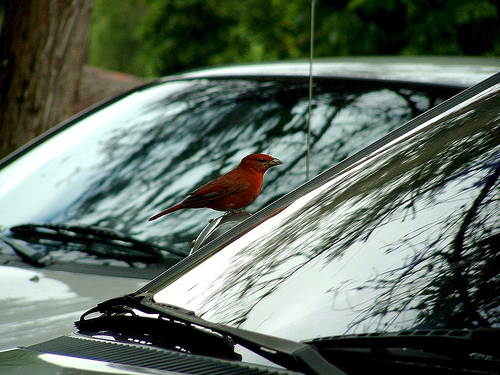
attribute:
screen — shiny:
[90, 74, 499, 374]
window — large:
[1, 80, 484, 292]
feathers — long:
[145, 200, 182, 229]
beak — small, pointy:
[269, 156, 284, 167]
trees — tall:
[0, 4, 499, 158]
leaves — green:
[86, 0, 498, 85]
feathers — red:
[189, 180, 254, 202]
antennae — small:
[252, 12, 371, 129]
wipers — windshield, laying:
[26, 212, 182, 261]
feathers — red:
[182, 171, 255, 223]